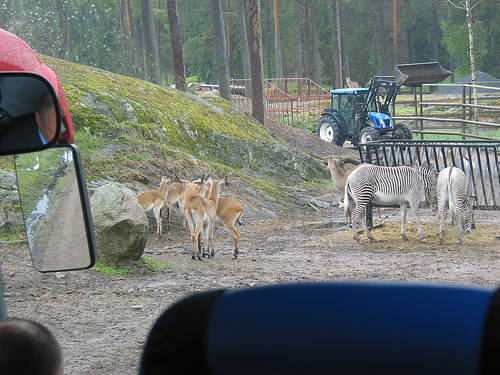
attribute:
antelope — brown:
[179, 175, 225, 262]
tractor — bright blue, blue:
[315, 72, 416, 154]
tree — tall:
[239, 1, 269, 124]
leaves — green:
[440, 17, 494, 78]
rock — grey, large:
[85, 177, 149, 267]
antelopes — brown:
[134, 168, 251, 262]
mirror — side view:
[13, 147, 102, 278]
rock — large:
[2, 48, 332, 242]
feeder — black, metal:
[355, 135, 500, 216]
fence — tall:
[378, 73, 499, 143]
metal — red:
[226, 73, 331, 124]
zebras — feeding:
[333, 155, 485, 246]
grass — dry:
[2, 53, 316, 239]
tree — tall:
[166, 0, 190, 90]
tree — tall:
[140, 2, 164, 82]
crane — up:
[358, 58, 461, 121]